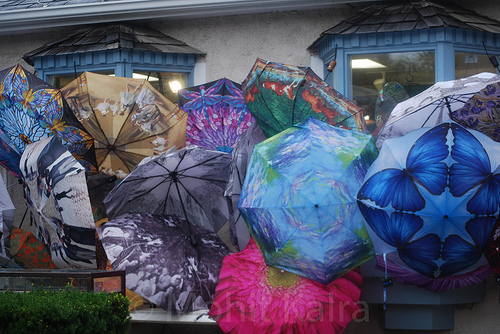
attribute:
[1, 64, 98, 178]
umbrella — black, yellow, Blue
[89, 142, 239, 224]
umbrella — black, gray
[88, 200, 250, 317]
umbrella — purple, white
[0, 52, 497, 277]
umbrellas — open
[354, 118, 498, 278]
umbrella — light blue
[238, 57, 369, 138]
umbrella — green, red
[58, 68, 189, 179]
umbrella — color brown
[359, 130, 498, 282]
umbrella — multicolor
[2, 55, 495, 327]
umbrellas — colorful, open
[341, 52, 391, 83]
light — white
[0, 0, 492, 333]
building — dirty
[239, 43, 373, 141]
umbrella — multicolor, upside down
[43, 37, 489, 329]
umbrellas — large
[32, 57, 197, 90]
paint — blue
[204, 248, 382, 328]
umbrella — pink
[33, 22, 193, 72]
top — black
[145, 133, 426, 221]
umbrellas — patterned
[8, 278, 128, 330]
grass — green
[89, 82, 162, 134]
people — dancing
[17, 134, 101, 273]
umbrella — black, gray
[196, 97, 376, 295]
umbrella — blue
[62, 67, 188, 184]
brownumbrella — brown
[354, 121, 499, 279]
motifs — dark blue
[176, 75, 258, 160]
umbrella — pink, blue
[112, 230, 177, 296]
image — singer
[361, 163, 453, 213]
butterfly — blue